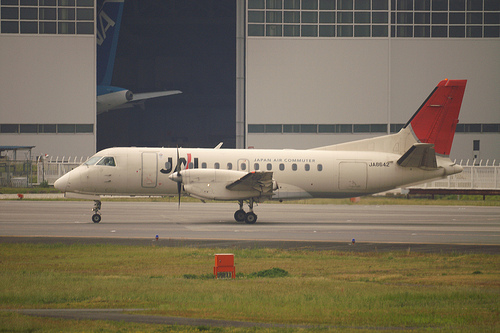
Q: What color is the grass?
A: Green.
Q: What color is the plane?
A: Blue, white and red.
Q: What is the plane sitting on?
A: A runway.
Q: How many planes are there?
A: One.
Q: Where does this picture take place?
A: On an airport runway.